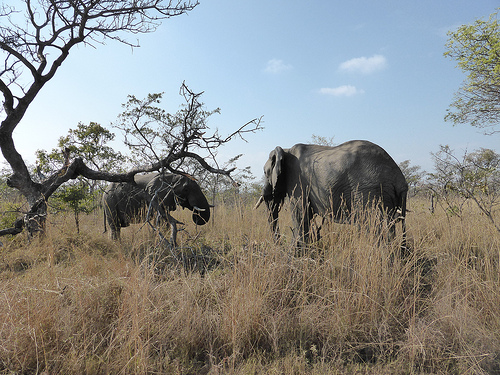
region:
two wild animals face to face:
[15, 10, 480, 345]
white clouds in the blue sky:
[255, 40, 395, 100]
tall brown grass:
[10, 275, 145, 365]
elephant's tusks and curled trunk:
[190, 200, 215, 225]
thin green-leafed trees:
[425, 20, 495, 235]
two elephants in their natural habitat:
[15, 30, 471, 355]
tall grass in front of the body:
[300, 185, 407, 276]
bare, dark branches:
[0, 42, 55, 247]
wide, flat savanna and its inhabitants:
[15, 25, 485, 355]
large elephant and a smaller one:
[95, 112, 417, 267]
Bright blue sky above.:
[210, 15, 378, 50]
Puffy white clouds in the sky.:
[320, 42, 396, 123]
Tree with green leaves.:
[436, 12, 494, 144]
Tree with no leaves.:
[12, 8, 191, 63]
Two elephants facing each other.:
[90, 125, 425, 234]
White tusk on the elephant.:
[245, 186, 274, 216]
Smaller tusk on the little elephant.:
[183, 195, 217, 229]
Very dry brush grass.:
[50, 265, 285, 345]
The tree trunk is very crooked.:
[0, 75, 55, 227]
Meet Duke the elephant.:
[241, 125, 421, 247]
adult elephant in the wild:
[249, 144, 431, 266]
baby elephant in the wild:
[98, 161, 247, 254]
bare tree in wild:
[0, 0, 193, 281]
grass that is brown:
[0, 253, 499, 374]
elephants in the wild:
[86, 115, 433, 286]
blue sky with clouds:
[2, 1, 497, 131]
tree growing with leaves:
[441, 7, 499, 150]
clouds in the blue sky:
[248, 13, 398, 115]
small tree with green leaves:
[34, 112, 108, 214]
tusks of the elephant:
[188, 202, 211, 215]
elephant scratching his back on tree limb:
[95, 164, 210, 244]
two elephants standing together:
[98, 132, 415, 254]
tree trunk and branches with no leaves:
[0, 5, 229, 244]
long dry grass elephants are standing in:
[0, 209, 497, 373]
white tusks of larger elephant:
[252, 190, 287, 216]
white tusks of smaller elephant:
[190, 202, 217, 213]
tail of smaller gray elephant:
[97, 207, 107, 233]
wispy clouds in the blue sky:
[253, 42, 391, 103]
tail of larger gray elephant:
[395, 193, 418, 248]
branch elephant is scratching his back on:
[61, 113, 238, 193]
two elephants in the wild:
[11, 46, 496, 327]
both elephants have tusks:
[54, 94, 434, 259]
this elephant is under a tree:
[28, 77, 241, 264]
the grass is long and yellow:
[61, 125, 482, 302]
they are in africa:
[43, 108, 477, 319]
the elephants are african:
[56, 103, 452, 285]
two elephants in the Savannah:
[29, 88, 436, 313]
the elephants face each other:
[37, 59, 469, 297]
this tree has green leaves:
[408, 14, 495, 91]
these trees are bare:
[31, 25, 233, 157]